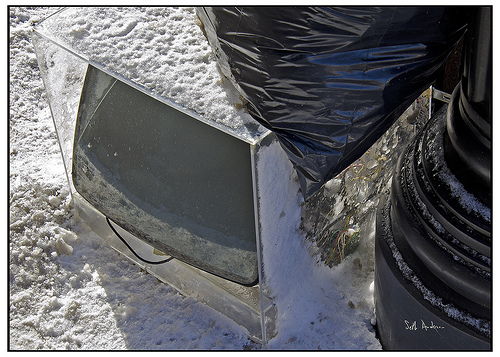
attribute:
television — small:
[28, 6, 437, 346]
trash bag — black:
[196, 8, 471, 198]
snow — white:
[27, 246, 99, 321]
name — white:
[401, 312, 449, 334]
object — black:
[411, 65, 498, 308]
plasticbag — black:
[188, 0, 479, 197]